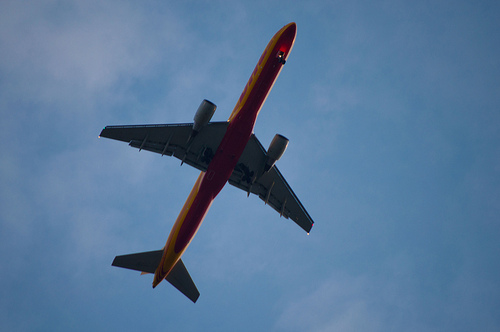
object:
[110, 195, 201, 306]
orange tail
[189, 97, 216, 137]
engine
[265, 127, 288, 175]
engine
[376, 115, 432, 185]
ground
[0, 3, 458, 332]
clouds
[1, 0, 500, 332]
blue sky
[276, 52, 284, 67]
light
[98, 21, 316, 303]
airplane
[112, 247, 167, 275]
wings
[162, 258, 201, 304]
wings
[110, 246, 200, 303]
tail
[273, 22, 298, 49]
nose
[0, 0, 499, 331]
air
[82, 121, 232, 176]
wing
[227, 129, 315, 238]
wing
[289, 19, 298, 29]
point